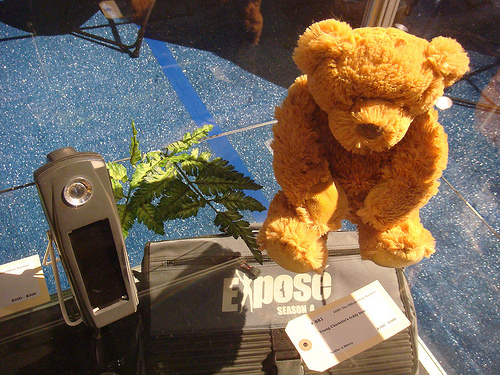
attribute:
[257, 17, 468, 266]
teddy bear — brown, plushie, gold, stuffed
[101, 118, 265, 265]
leaves — green, artificial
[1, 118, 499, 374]
table — glass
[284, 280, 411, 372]
tag — printed, beige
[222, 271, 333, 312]
word — white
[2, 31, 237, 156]
floor — tile, blue, glittery, spotted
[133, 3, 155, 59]
leg — black metal